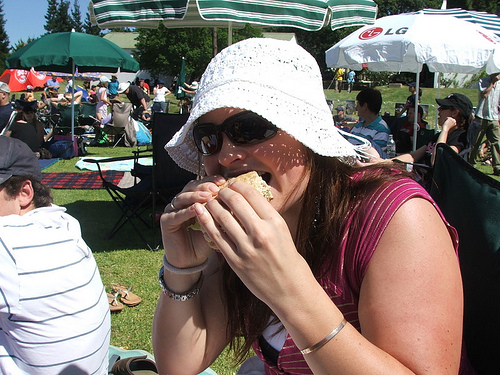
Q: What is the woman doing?
A: Eating a sandwich.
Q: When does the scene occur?
A: Daytime.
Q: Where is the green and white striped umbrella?
A: Behind the woman.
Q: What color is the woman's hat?
A: White.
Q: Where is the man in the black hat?
A: To the left.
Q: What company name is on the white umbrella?
A: LG.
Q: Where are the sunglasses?
A: On the woman's face.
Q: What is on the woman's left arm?
A: A silver bracelet.